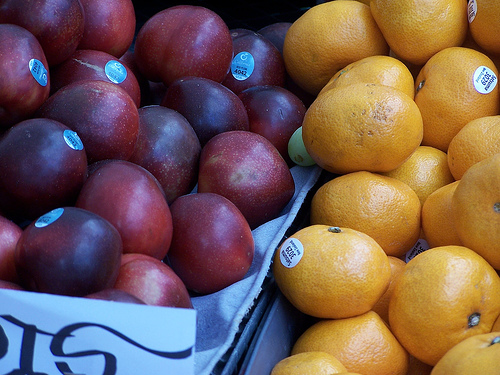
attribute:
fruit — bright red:
[235, 81, 309, 155]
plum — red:
[9, 201, 124, 291]